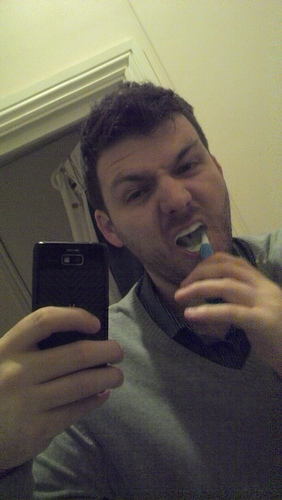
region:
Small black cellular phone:
[8, 232, 130, 365]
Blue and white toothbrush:
[190, 223, 233, 330]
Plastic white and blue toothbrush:
[184, 214, 233, 341]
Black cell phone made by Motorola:
[16, 240, 137, 409]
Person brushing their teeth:
[0, 79, 280, 418]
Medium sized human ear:
[93, 200, 126, 256]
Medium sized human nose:
[153, 167, 202, 221]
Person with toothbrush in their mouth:
[32, 67, 279, 361]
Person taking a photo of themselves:
[1, 77, 280, 419]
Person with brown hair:
[0, 81, 277, 460]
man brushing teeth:
[76, 77, 255, 308]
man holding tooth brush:
[84, 118, 264, 341]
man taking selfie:
[22, 137, 259, 367]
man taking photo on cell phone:
[19, 82, 265, 363]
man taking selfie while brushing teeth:
[16, 57, 248, 357]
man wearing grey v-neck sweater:
[21, 233, 280, 482]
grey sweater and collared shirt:
[5, 260, 280, 438]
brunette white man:
[29, 58, 267, 300]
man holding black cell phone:
[0, 192, 154, 429]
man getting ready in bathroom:
[0, 53, 280, 374]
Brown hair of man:
[73, 87, 190, 151]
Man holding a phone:
[3, 135, 272, 382]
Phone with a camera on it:
[30, 243, 114, 304]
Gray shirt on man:
[121, 324, 275, 443]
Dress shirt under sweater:
[137, 285, 250, 368]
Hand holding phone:
[9, 306, 108, 427]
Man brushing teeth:
[92, 110, 266, 322]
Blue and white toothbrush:
[191, 225, 227, 272]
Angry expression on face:
[94, 108, 235, 270]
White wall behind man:
[228, 125, 277, 191]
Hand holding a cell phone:
[1, 215, 109, 437]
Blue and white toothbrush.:
[190, 218, 214, 255]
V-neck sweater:
[115, 282, 272, 481]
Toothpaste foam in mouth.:
[167, 212, 210, 248]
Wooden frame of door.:
[0, 34, 188, 93]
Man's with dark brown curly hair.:
[67, 72, 217, 177]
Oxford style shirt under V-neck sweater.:
[126, 256, 180, 334]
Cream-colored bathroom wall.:
[118, 0, 273, 66]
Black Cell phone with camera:
[30, 236, 106, 287]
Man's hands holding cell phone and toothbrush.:
[34, 199, 271, 437]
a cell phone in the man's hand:
[23, 234, 115, 321]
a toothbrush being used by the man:
[190, 226, 214, 279]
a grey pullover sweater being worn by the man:
[120, 336, 241, 425]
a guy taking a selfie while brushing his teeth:
[25, 97, 252, 368]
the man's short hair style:
[70, 83, 212, 126]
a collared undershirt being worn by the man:
[136, 287, 183, 340]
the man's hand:
[2, 311, 115, 458]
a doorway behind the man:
[2, 67, 77, 206]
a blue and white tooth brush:
[200, 235, 216, 272]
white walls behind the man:
[177, 11, 264, 66]